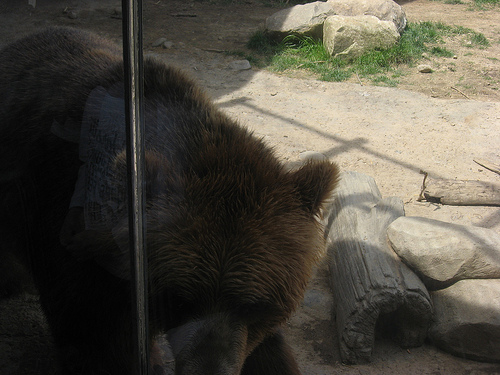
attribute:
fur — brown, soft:
[8, 28, 363, 358]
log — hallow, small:
[298, 151, 447, 359]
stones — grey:
[239, 2, 410, 49]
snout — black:
[150, 303, 257, 374]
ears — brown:
[97, 121, 353, 228]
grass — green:
[245, 19, 467, 101]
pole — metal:
[108, 0, 161, 366]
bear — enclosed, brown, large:
[0, 30, 329, 374]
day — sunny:
[4, 4, 499, 283]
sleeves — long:
[57, 75, 104, 231]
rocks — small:
[144, 15, 261, 70]